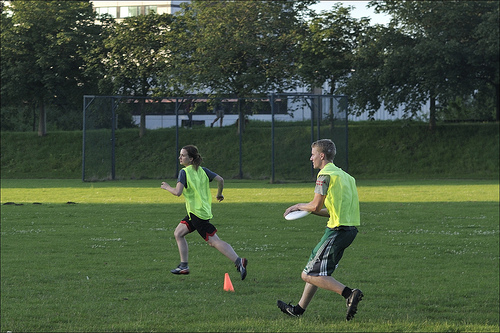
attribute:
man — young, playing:
[274, 137, 367, 323]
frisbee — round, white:
[280, 211, 313, 225]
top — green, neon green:
[178, 164, 216, 224]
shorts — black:
[300, 226, 360, 280]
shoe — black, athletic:
[344, 284, 363, 321]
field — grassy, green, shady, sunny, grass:
[1, 176, 500, 332]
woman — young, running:
[157, 142, 250, 283]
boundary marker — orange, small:
[219, 267, 237, 295]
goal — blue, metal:
[77, 91, 352, 186]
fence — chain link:
[318, 87, 349, 121]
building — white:
[4, 1, 481, 131]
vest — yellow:
[316, 163, 363, 229]